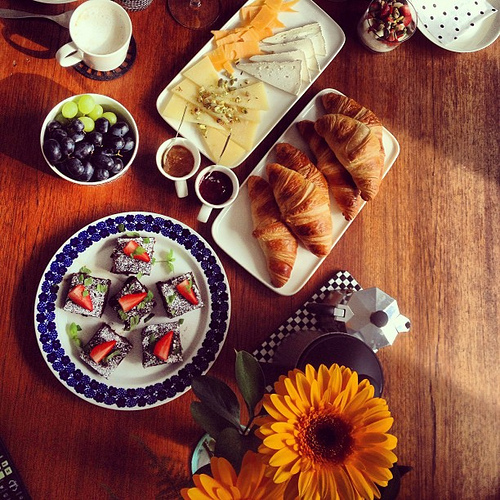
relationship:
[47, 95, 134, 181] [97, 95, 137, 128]
grapes inside of bowl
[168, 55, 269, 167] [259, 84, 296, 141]
cheese on plate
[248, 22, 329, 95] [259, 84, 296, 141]
cheese on plate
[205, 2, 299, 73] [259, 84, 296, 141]
cheese on plate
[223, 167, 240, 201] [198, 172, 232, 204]
cup of jam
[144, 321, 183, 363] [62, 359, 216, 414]
brownie on plate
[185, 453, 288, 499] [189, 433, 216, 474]
flower in vase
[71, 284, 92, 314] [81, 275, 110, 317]
strawberry on brownie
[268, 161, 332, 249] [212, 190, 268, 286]
bread on plate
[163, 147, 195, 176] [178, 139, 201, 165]
jam in cup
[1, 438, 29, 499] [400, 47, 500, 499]
remote on table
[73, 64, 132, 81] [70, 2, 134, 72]
coaster under mug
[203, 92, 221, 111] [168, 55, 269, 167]
nuts on cheese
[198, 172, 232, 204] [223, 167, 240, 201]
jam in cup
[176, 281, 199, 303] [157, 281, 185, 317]
strawberry on brownie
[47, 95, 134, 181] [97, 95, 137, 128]
grapes in bowl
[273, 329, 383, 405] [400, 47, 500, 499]
kettle on table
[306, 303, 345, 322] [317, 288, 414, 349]
handle on bottle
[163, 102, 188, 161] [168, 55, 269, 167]
toothepick inside th cheese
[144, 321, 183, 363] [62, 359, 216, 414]
rownie on plate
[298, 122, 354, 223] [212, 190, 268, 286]
bread on plate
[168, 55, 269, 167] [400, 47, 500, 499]
cheese on table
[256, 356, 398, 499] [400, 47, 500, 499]
flower on table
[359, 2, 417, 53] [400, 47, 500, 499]
parfait on table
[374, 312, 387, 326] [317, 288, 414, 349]
knob on bottle